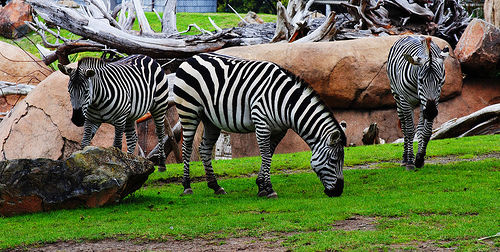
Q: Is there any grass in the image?
A: Yes, there is grass.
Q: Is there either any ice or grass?
A: Yes, there is grass.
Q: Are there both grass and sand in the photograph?
A: No, there is grass but no sand.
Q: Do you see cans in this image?
A: No, there are no cans.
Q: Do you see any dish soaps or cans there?
A: No, there are no cans or dish soaps.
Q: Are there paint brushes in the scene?
A: No, there are no paint brushes.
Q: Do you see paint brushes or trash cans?
A: No, there are no paint brushes or trash cans.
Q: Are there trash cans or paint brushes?
A: No, there are no paint brushes or trash cans.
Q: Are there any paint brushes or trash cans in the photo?
A: No, there are no paint brushes or trash cans.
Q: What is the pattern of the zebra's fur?
A: The fur is striped.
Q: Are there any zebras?
A: Yes, there is a zebra.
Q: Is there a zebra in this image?
A: Yes, there is a zebra.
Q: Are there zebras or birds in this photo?
A: Yes, there is a zebra.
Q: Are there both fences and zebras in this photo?
A: No, there is a zebra but no fences.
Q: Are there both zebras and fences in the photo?
A: No, there is a zebra but no fences.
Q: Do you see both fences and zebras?
A: No, there is a zebra but no fences.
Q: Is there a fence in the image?
A: No, there are no fences.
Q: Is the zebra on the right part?
A: Yes, the zebra is on the right of the image.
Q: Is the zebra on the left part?
A: No, the zebra is on the right of the image.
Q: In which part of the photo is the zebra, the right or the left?
A: The zebra is on the right of the image.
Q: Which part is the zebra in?
A: The zebra is on the right of the image.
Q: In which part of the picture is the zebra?
A: The zebra is on the right of the image.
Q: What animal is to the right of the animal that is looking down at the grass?
A: The animal is a zebra.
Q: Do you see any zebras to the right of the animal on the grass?
A: Yes, there is a zebra to the right of the animal.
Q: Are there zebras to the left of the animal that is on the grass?
A: No, the zebra is to the right of the animal.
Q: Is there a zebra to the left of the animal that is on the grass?
A: No, the zebra is to the right of the animal.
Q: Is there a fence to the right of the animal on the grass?
A: No, there is a zebra to the right of the animal.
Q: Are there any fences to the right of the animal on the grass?
A: No, there is a zebra to the right of the animal.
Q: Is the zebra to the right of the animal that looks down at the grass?
A: Yes, the zebra is to the right of the animal.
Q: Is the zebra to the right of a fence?
A: No, the zebra is to the right of the animal.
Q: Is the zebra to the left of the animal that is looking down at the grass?
A: No, the zebra is to the right of the animal.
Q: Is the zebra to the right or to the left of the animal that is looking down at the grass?
A: The zebra is to the right of the animal.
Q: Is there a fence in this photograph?
A: No, there are no fences.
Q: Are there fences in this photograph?
A: No, there are no fences.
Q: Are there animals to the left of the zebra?
A: Yes, there is an animal to the left of the zebra.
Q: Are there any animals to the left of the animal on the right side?
A: Yes, there is an animal to the left of the zebra.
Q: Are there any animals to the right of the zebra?
A: No, the animal is to the left of the zebra.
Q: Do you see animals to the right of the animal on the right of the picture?
A: No, the animal is to the left of the zebra.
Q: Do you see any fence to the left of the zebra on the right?
A: No, there is an animal to the left of the zebra.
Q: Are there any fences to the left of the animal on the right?
A: No, there is an animal to the left of the zebra.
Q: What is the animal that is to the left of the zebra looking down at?
A: The animal is looking down at the grass.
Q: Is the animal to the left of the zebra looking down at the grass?
A: Yes, the animal is looking down at the grass.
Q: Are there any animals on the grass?
A: Yes, there is an animal on the grass.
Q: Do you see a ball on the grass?
A: No, there is an animal on the grass.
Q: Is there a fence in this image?
A: No, there are no fences.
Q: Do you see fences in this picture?
A: No, there are no fences.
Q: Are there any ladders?
A: No, there are no ladders.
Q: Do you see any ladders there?
A: No, there are no ladders.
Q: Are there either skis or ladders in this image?
A: No, there are no ladders or skis.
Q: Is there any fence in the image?
A: No, there are no fences.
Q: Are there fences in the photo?
A: No, there are no fences.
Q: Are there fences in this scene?
A: No, there are no fences.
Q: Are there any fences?
A: No, there are no fences.